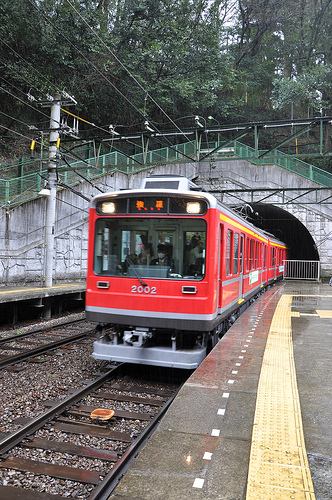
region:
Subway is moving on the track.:
[76, 170, 288, 378]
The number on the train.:
[121, 269, 172, 304]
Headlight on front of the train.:
[87, 185, 123, 221]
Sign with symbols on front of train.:
[122, 184, 176, 231]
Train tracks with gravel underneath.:
[8, 326, 85, 498]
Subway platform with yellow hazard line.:
[261, 253, 309, 453]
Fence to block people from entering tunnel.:
[273, 249, 324, 288]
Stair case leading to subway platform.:
[189, 139, 331, 177]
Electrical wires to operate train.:
[11, 88, 233, 158]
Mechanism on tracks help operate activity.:
[74, 397, 127, 435]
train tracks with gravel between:
[9, 318, 128, 420]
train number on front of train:
[127, 277, 164, 301]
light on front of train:
[94, 193, 204, 223]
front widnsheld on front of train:
[92, 215, 211, 297]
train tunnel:
[222, 193, 329, 290]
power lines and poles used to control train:
[7, 52, 330, 204]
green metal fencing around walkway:
[11, 116, 239, 196]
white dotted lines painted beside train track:
[162, 313, 262, 499]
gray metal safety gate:
[279, 251, 328, 282]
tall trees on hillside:
[101, 13, 314, 149]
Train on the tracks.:
[59, 156, 294, 425]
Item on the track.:
[87, 377, 151, 443]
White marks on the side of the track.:
[196, 364, 288, 421]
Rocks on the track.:
[71, 361, 150, 426]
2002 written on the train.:
[120, 276, 184, 306]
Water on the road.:
[290, 270, 315, 345]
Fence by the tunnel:
[285, 239, 329, 297]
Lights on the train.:
[91, 198, 205, 219]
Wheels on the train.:
[194, 318, 252, 358]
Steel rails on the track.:
[19, 334, 107, 375]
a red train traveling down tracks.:
[78, 176, 288, 371]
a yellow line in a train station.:
[243, 290, 318, 498]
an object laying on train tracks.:
[81, 404, 127, 438]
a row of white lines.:
[190, 294, 278, 492]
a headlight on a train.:
[182, 197, 207, 221]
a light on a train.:
[117, 197, 172, 217]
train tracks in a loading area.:
[1, 362, 190, 498]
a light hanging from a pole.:
[25, 162, 61, 204]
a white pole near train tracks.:
[43, 190, 65, 294]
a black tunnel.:
[221, 194, 321, 270]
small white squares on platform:
[202, 409, 238, 435]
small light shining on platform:
[175, 445, 197, 472]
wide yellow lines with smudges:
[249, 414, 315, 475]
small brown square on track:
[78, 401, 124, 426]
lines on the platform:
[170, 423, 261, 452]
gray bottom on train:
[86, 340, 216, 391]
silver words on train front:
[119, 280, 167, 300]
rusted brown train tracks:
[49, 369, 132, 464]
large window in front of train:
[88, 210, 217, 295]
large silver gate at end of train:
[278, 248, 329, 287]